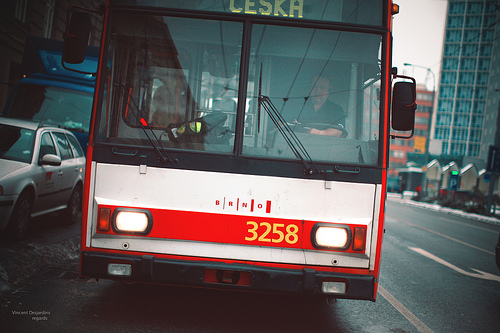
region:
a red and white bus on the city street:
[58, 0, 418, 302]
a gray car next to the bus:
[0, 113, 85, 226]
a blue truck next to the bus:
[2, 34, 111, 153]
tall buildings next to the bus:
[363, 0, 498, 166]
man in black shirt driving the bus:
[279, 73, 346, 137]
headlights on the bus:
[114, 206, 348, 248]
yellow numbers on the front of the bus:
[245, 220, 299, 244]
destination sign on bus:
[228, 0, 304, 18]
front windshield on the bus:
[94, 5, 383, 167]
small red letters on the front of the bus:
[212, 199, 262, 209]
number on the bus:
[236, 220, 308, 251]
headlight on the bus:
[312, 224, 347, 249]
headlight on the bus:
[355, 224, 366, 254]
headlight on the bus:
[119, 211, 156, 234]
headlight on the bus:
[89, 205, 113, 235]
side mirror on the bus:
[385, 78, 415, 146]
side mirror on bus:
[62, 10, 87, 76]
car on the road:
[0, 130, 83, 216]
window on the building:
[453, 115, 468, 122]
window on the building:
[449, 115, 466, 127]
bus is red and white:
[71, 4, 409, 308]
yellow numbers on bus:
[228, 220, 317, 255]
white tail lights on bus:
[102, 201, 373, 259]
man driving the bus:
[273, 60, 361, 145]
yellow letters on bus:
[209, 0, 336, 25]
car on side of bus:
[0, 108, 90, 233]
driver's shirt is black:
[298, 96, 353, 142]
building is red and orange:
[385, 82, 435, 159]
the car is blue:
[9, 37, 101, 145]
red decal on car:
[37, 161, 57, 182]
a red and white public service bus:
[59, 1, 421, 301]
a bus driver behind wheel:
[288, 71, 347, 135]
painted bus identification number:
[242, 219, 299, 244]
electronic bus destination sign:
[161, 0, 341, 17]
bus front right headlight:
[112, 208, 147, 232]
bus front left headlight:
[313, 224, 347, 249]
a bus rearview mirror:
[392, 80, 415, 132]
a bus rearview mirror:
[58, 10, 91, 62]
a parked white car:
[0, 117, 87, 232]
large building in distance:
[429, 0, 497, 164]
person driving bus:
[28, 6, 425, 305]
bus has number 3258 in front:
[50, 5, 422, 315]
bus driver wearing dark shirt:
[265, 59, 373, 183]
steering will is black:
[277, 103, 357, 153]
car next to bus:
[2, 90, 136, 267]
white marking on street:
[379, 182, 499, 322]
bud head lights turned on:
[71, 113, 422, 310]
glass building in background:
[419, 6, 499, 193]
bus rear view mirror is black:
[368, 39, 445, 186]